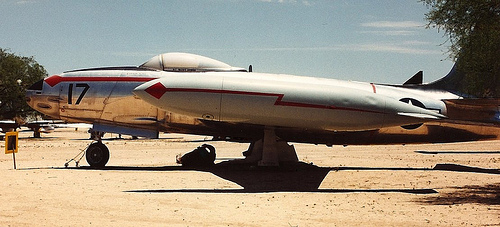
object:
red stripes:
[166, 88, 396, 116]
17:
[68, 83, 91, 105]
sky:
[0, 0, 499, 86]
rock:
[313, 202, 318, 205]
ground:
[0, 123, 499, 226]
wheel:
[85, 141, 110, 165]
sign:
[5, 131, 18, 153]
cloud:
[359, 20, 445, 28]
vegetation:
[418, 0, 500, 93]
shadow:
[401, 182, 499, 205]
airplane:
[22, 13, 499, 167]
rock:
[173, 209, 180, 212]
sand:
[0, 119, 499, 226]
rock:
[312, 203, 317, 206]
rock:
[40, 156, 46, 158]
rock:
[328, 199, 334, 202]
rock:
[422, 218, 432, 224]